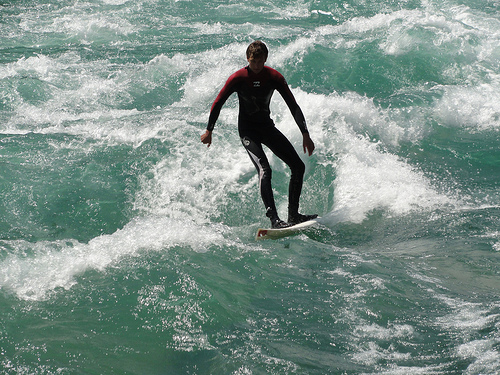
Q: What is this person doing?
A: Surfing.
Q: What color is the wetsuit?
A: Black.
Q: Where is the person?
A: Ocean.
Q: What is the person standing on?
A: Surfboard.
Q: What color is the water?
A: Blue and green.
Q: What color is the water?
A: Blue.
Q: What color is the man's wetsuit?
A: Red.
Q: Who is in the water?
A: A man.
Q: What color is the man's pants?
A: Black.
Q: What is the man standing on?
A: A surfboard.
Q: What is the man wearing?
A: A wetsuit.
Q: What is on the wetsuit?
A: White writing.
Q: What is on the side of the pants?
A: A white stripe.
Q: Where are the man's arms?
A: Sticking out.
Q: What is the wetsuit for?
A: To go in the water.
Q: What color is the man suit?
A: Black, red and white.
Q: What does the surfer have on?
A: Wetsuit.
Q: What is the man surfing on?
A: White board.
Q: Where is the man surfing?
A: Beach.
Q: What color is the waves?
A: White.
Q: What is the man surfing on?
A: Powerful waves.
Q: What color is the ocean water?
A: Blue.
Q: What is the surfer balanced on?
A: White surfboard.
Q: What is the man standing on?
A: Surfboard.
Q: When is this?
A: Daytime.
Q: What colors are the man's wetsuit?
A: Black and white.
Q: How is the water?
A: Wavey.